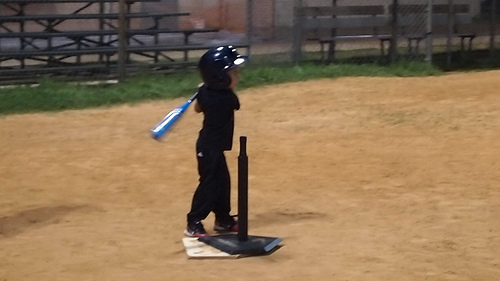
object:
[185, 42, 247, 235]
boy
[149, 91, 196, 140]
bat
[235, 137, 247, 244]
tee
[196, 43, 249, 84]
helmet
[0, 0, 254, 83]
bleachers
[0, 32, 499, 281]
field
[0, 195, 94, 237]
shadow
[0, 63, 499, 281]
ground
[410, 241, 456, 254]
prints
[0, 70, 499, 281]
dirt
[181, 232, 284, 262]
plate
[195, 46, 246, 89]
head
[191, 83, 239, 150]
shirt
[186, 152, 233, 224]
pants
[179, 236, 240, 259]
base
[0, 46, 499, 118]
grass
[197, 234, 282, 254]
triangle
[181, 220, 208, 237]
shoes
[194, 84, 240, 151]
attire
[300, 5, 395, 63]
benches